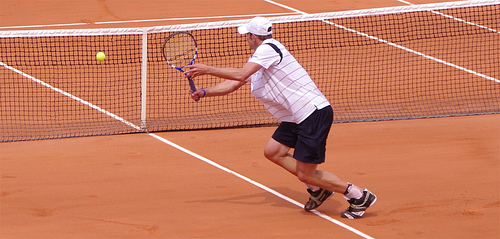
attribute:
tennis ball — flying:
[96, 50, 106, 63]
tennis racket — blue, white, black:
[162, 31, 198, 97]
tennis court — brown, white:
[2, 1, 500, 236]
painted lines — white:
[162, 139, 252, 180]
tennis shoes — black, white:
[342, 187, 378, 219]